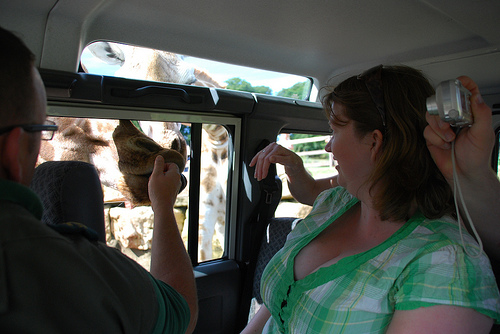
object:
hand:
[422, 74, 494, 178]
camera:
[426, 77, 475, 128]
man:
[0, 27, 200, 334]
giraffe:
[35, 116, 187, 207]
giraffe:
[86, 41, 229, 165]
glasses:
[0, 119, 58, 141]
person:
[422, 74, 500, 261]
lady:
[240, 64, 498, 334]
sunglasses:
[356, 63, 389, 126]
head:
[324, 65, 438, 201]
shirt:
[257, 184, 499, 334]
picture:
[0, 0, 500, 334]